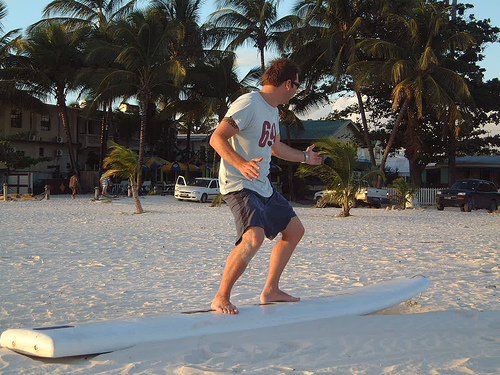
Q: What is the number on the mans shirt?
A: 69.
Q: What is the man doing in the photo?
A: Practicing surfacing.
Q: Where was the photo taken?
A: On the beach.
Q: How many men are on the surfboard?
A: One.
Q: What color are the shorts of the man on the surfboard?
A: Blue.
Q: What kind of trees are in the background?
A: Palm trees.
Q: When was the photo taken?
A: Summertime.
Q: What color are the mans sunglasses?
A: Black.